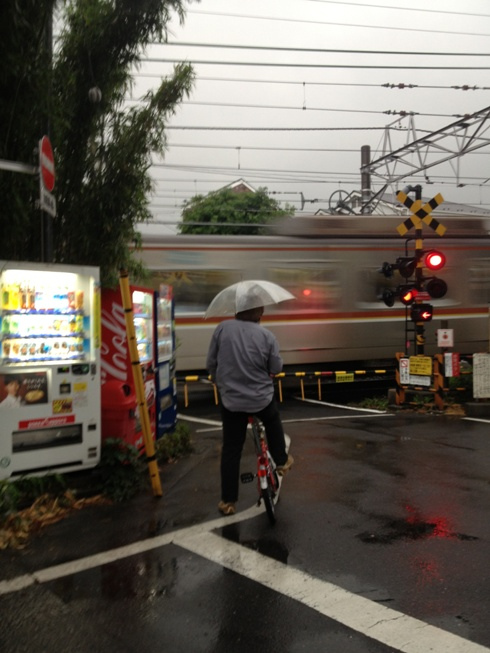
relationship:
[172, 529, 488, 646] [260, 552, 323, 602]
line on ground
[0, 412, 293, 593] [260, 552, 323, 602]
line on ground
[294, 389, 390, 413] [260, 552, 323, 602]
line on ground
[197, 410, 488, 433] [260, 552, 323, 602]
line on ground